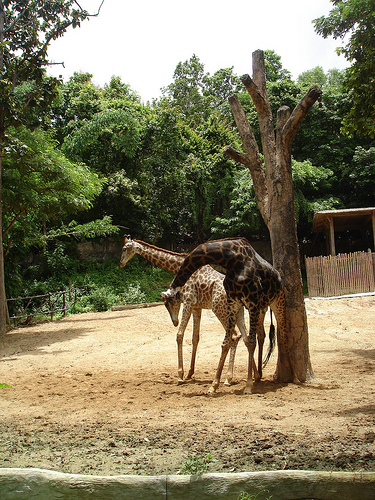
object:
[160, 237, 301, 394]
giraffes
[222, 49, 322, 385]
tree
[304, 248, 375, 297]
fence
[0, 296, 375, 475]
sand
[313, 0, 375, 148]
trees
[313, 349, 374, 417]
shadows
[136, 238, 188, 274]
neck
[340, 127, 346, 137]
leaves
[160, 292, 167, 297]
horns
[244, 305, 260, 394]
legs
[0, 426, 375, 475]
dirt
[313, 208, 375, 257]
shelter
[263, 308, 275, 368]
tail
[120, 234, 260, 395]
giraffe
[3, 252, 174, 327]
bushes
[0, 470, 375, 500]
wall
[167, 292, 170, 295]
ears